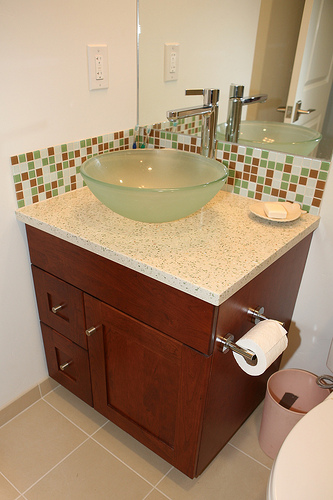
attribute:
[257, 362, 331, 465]
basket — pink, wastepaper, peach, sitting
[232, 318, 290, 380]
paper — rolled, mounted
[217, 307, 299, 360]
dispenser — chrome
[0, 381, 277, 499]
floor — tiled, beige, tan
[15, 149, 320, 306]
countertop — granite, vanity, speckled, marble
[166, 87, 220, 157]
faucet — chrome, silver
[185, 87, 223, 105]
handle — chrome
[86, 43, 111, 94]
outlet — elecrtical, rectangular, electrical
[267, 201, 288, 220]
soap — bar, sitting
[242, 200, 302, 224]
dish — small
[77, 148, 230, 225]
sink — glass, sitting, red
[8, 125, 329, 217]
backsplash — white, green, brown, red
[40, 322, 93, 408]
drawer — bottom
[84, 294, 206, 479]
door — center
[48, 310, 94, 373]
knobs — silver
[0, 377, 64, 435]
border — tiled